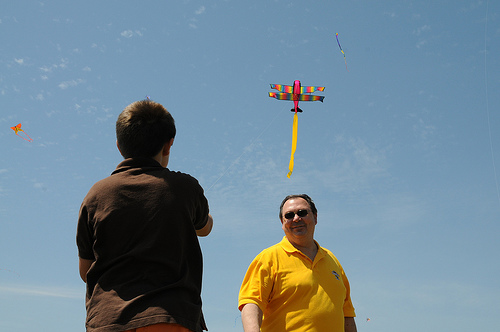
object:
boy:
[76, 99, 214, 332]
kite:
[267, 80, 325, 179]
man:
[237, 194, 357, 331]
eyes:
[284, 211, 295, 219]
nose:
[293, 214, 302, 223]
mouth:
[290, 225, 306, 231]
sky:
[0, 0, 499, 331]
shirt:
[237, 236, 356, 332]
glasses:
[281, 209, 313, 219]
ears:
[279, 212, 283, 224]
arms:
[237, 266, 278, 331]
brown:
[89, 168, 194, 331]